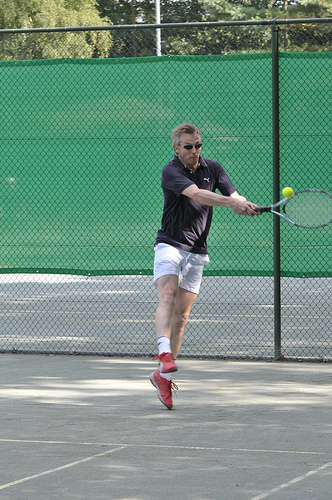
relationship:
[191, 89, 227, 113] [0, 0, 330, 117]
grey chain chain link tall fence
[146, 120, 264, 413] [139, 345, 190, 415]
man red tennis shoes red shoes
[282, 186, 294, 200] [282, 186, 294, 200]
ball yellow ball ball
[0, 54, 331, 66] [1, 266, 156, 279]
green barrier tied on fence barrier tied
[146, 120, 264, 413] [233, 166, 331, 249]
man holding racket tennis racket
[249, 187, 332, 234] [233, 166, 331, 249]
racket racket strikes ball strikes a ball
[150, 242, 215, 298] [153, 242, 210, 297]
white shorts man wearing shorts white shorts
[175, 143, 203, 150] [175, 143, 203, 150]
dark sunglasses sunglasses on nose dark sunglasses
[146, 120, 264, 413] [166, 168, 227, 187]
man wearing polo shirt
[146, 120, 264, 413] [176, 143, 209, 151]
man with dark sunglasses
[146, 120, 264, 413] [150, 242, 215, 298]
man with white shorts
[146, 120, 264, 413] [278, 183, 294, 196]
man to hit ball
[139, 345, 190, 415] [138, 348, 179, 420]
red shoes cover mans feet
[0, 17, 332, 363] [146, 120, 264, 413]
black wire fence behind man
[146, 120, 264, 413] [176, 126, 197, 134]
man has gray hair on head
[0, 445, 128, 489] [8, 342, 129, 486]
white lines on court on court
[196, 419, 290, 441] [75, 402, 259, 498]
gray asphalt on court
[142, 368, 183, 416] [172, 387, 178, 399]
sneaker with red sneaker laces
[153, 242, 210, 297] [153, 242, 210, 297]
white shorts wearing white shorts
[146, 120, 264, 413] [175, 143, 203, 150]
man wearing dark sunglasses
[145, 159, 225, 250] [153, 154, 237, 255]
man wearing polo shirt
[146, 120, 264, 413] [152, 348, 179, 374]
man wearing red shoes